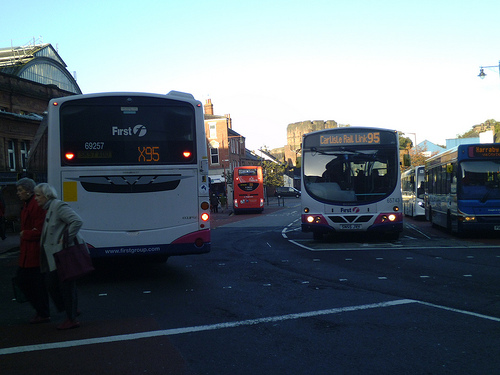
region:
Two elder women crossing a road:
[12, 174, 94, 329]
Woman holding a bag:
[32, 180, 97, 334]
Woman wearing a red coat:
[7, 177, 52, 329]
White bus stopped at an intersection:
[298, 123, 409, 243]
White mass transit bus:
[20, 85, 215, 267]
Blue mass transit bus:
[424, 138, 499, 236]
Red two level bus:
[227, 161, 266, 216]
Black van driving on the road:
[272, 184, 301, 199]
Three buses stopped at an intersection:
[297, 126, 499, 243]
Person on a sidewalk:
[207, 189, 222, 216]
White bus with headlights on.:
[294, 122, 414, 242]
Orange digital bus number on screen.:
[293, 118, 410, 245]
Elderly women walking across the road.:
[5, 171, 99, 333]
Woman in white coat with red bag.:
[29, 180, 101, 337]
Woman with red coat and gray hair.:
[8, 178, 48, 325]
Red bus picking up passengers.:
[230, 157, 267, 218]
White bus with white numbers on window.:
[41, 90, 218, 259]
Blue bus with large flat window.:
[423, 135, 498, 236]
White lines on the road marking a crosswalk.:
[0, 294, 498, 364]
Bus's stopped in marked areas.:
[31, 85, 498, 261]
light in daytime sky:
[1, 2, 496, 141]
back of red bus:
[234, 166, 264, 208]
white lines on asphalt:
[3, 296, 497, 372]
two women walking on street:
[13, 178, 93, 330]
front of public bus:
[299, 128, 403, 235]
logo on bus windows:
[112, 121, 147, 137]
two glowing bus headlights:
[306, 213, 399, 224]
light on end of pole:
[476, 64, 498, 79]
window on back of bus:
[58, 95, 198, 169]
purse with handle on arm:
[53, 228, 95, 281]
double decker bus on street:
[221, 159, 280, 218]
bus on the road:
[286, 115, 408, 248]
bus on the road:
[27, 85, 234, 280]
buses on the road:
[410, 134, 499, 246]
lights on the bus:
[298, 209, 403, 229]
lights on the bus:
[57, 143, 210, 166]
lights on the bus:
[231, 197, 271, 211]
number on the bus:
[81, 134, 112, 152]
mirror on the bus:
[400, 146, 419, 172]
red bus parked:
[230, 163, 263, 213]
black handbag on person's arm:
[52, 228, 96, 282]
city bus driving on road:
[297, 125, 404, 239]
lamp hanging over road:
[475, 65, 499, 79]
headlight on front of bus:
[303, 213, 317, 225]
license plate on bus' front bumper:
[341, 223, 365, 230]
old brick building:
[270, 117, 342, 169]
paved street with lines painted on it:
[0, 200, 498, 374]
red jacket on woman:
[15, 198, 45, 268]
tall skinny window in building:
[207, 140, 219, 166]